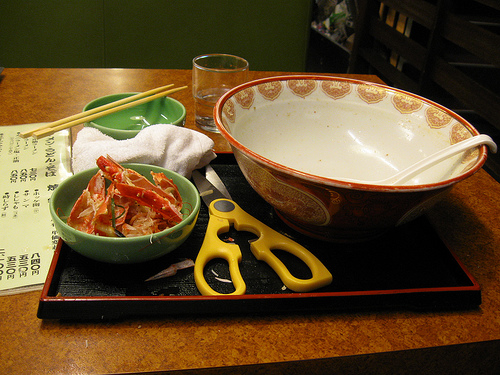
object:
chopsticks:
[19, 72, 188, 141]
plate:
[37, 151, 481, 319]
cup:
[190, 53, 249, 133]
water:
[193, 87, 232, 133]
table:
[0, 68, 499, 374]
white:
[297, 113, 399, 163]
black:
[332, 256, 444, 279]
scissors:
[191, 164, 333, 296]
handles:
[194, 198, 333, 295]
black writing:
[18, 253, 41, 278]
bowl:
[212, 74, 488, 239]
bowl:
[49, 162, 201, 260]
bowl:
[81, 92, 186, 140]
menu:
[0, 122, 74, 295]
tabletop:
[0, 67, 492, 372]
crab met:
[56, 154, 193, 254]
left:
[0, 0, 56, 375]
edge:
[40, 286, 480, 302]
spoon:
[333, 134, 496, 185]